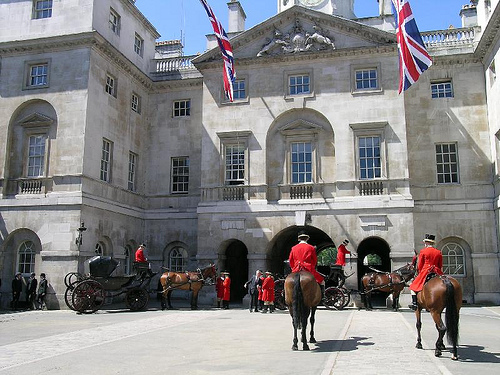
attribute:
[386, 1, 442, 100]
flag — british, union, red, blue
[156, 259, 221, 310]
horse — brown, large, standing, bay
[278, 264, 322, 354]
horse — brown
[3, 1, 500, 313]
building — impressive, brick, stone, large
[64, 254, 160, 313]
carriage — charcoal, horse drawn, black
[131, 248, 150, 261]
shirt — red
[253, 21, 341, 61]
figure — symbolic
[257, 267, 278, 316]
person — talking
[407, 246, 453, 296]
uniform — red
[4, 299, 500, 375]
pavement — gray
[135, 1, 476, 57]
sky — blue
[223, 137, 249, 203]
window — open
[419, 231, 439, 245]
hat — black